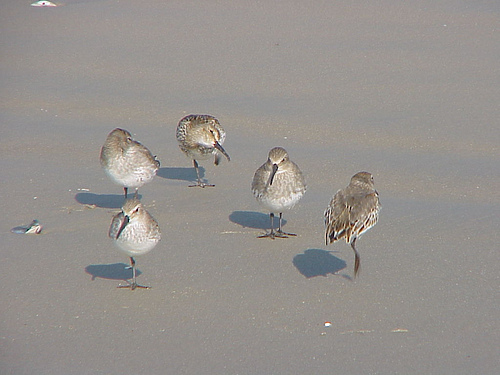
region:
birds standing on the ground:
[84, 85, 434, 300]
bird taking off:
[321, 166, 401, 301]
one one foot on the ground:
[185, 157, 227, 191]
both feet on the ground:
[255, 213, 289, 238]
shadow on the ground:
[287, 240, 350, 287]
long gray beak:
[111, 215, 136, 242]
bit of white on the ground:
[322, 313, 337, 330]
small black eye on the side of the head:
[130, 204, 142, 216]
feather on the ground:
[11, 204, 46, 243]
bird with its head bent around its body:
[89, 117, 171, 198]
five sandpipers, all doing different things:
[78, 99, 395, 315]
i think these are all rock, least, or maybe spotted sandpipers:
[71, 93, 391, 304]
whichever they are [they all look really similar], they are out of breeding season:
[90, 102, 392, 302]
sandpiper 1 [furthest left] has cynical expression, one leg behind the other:
[80, 191, 162, 292]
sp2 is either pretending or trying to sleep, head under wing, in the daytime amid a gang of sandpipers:
[90, 121, 165, 207]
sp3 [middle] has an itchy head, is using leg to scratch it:
[171, 105, 237, 192]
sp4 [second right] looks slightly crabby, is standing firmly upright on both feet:
[245, 143, 312, 246]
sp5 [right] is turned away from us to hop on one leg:
[315, 168, 385, 281]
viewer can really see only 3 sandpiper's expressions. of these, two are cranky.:
[107, 121, 301, 258]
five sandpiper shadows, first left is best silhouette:
[55, 157, 362, 326]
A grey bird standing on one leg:
[111, 196, 159, 291]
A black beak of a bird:
[216, 142, 230, 162]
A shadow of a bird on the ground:
[293, 248, 348, 283]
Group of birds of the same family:
[81, 103, 403, 292]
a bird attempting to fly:
[323, 158, 397, 304]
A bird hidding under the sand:
[7, 211, 63, 248]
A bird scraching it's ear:
[169, 105, 248, 188]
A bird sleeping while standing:
[103, 119, 164, 196]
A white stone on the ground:
[22, 1, 67, 21]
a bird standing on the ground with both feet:
[249, 131, 311, 252]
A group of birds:
[87, 90, 418, 291]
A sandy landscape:
[2, 0, 488, 370]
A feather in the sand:
[8, 220, 63, 250]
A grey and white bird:
[102, 190, 187, 333]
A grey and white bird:
[95, 116, 165, 207]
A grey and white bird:
[172, 101, 227, 206]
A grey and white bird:
[245, 135, 315, 281]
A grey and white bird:
[320, 150, 395, 302]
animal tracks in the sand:
[47, 190, 98, 222]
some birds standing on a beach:
[62, 82, 415, 324]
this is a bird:
[323, 158, 401, 242]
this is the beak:
[268, 161, 280, 183]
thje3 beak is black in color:
[268, 166, 278, 181]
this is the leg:
[263, 213, 300, 237]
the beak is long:
[115, 214, 125, 239]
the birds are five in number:
[94, 105, 406, 297]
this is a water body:
[299, 36, 459, 110]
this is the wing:
[346, 201, 371, 228]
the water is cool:
[301, 59, 370, 80]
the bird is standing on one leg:
[121, 256, 144, 298]